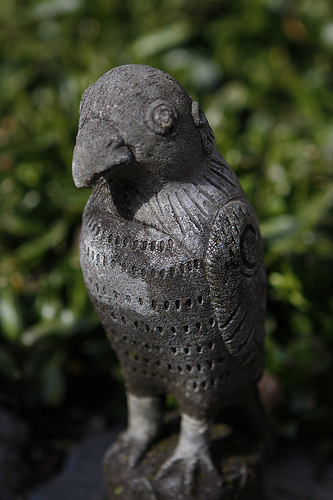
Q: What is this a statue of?
A: Bird.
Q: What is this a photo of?
A: A bird statue.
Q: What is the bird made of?
A: Stone.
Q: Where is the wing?
A: On the right.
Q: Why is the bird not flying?
A: It is not real.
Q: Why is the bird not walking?
A: It is not real.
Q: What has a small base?
A: The sculpture.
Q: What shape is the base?
A: Circular.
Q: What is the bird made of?
A: Stone.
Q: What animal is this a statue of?
A: A bird.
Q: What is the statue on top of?
A: A rock.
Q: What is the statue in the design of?
A: A bird.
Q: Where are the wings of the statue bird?
A: By its side.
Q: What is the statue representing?
A: A bird.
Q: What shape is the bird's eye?
A: Round.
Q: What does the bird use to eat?
A: Beak.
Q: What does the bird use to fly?
A: Wing.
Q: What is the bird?
A: A statue.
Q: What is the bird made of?
A: Stone.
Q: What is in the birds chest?
A: Holes.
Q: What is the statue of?
A: A bird.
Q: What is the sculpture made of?
A: Stone.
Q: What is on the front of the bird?
A: Holes.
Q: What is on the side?
A: Wings.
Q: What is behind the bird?
A: Trees.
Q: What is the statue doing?
A: Standing.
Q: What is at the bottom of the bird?
A: Feet.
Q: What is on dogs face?
A: Eye.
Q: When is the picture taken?
A: Daytime.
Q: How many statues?
A: One.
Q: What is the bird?
A: A statue.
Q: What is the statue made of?
A: Stone.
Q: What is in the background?
A: Green leaves.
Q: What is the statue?
A: A bird.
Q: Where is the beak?
A: On the face.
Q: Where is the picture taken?
A: Near the bird statue.